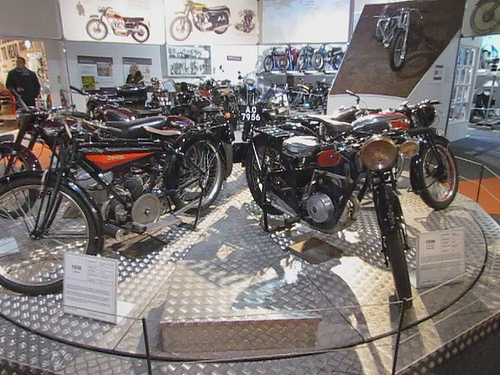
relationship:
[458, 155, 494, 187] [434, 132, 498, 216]
stripe on floor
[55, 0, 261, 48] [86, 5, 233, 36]
posters are motorcycles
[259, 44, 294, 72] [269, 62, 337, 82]
bike on wall shelf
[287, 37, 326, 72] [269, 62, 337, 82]
bike on wall shelf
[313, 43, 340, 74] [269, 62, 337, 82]
bike on wall shelf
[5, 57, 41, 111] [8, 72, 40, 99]
man wears coat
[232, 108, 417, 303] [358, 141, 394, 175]
motorcycle has head light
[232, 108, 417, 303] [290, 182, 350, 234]
motorcycle has engine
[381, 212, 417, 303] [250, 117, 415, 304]
front wheel on motorcycle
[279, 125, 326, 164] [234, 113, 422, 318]
seat on motorcycle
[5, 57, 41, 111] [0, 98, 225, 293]
man looks at motorbike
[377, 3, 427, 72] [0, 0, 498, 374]
bicycle on display in store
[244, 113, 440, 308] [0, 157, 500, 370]
bikes on display on wall shelf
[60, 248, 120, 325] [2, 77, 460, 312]
sign on display of motorbikes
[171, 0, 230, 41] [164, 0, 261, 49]
motorcycle on wall display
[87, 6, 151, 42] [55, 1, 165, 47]
motorcycle on wall display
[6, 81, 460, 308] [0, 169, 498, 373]
bikes on turntable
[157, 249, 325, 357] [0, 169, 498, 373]
pedestal on turntable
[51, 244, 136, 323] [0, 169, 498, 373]
sign on turntable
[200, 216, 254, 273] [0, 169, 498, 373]
shadow casted on turntable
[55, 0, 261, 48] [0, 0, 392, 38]
posters on wall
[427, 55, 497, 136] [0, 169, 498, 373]
fence around turntable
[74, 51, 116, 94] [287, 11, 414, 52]
sign on wall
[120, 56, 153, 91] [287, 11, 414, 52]
sign on wall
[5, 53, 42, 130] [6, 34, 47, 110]
man standing in doorway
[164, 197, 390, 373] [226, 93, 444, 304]
shadow cast by bike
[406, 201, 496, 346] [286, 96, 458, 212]
shadow cast by bike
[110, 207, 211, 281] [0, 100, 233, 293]
shadow cast by bike